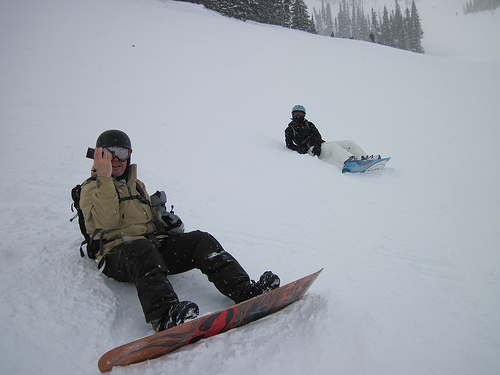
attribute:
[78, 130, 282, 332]
man — sitting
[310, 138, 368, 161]
pants — white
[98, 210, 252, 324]
pants — black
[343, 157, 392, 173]
board — blue, white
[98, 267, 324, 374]
board — red, black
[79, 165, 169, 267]
jacket — brown, tan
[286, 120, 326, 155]
jacket — black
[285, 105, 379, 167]
man — sitting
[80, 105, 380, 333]
men — resting, waiting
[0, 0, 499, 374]
snow — white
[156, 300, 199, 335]
boot — black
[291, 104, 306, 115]
helmet — blue